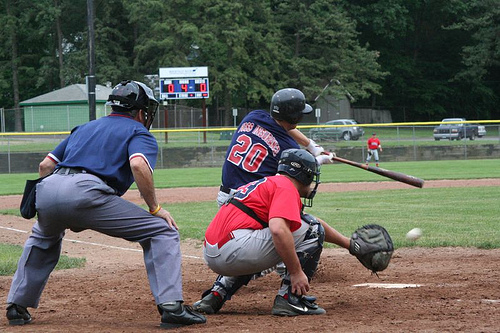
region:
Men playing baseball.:
[0, 7, 496, 327]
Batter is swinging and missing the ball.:
[218, 87, 421, 274]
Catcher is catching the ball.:
[182, 146, 423, 322]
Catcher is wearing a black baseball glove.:
[347, 222, 392, 272]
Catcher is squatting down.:
[185, 147, 391, 317]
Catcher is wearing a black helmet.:
[275, 146, 317, 184]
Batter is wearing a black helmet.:
[268, 85, 313, 121]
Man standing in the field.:
[361, 127, 383, 167]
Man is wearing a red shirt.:
[365, 135, 381, 148]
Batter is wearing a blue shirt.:
[217, 113, 299, 188]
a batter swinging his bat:
[207, 80, 430, 243]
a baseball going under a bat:
[351, 155, 441, 252]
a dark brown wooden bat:
[323, 148, 434, 196]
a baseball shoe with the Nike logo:
[268, 288, 327, 318]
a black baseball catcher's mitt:
[347, 218, 400, 275]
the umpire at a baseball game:
[8, 70, 209, 327]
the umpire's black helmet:
[105, 78, 161, 135]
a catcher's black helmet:
[273, 142, 328, 209]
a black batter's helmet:
[264, 84, 311, 135]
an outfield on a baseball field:
[363, 130, 385, 174]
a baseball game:
[6, 2, 496, 330]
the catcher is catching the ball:
[204, 157, 419, 328]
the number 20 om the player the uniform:
[227, 133, 265, 170]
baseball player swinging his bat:
[247, 95, 429, 188]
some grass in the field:
[428, 199, 497, 240]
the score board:
[160, 69, 212, 104]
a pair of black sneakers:
[3, 298, 203, 331]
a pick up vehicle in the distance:
[436, 118, 478, 144]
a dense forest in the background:
[4, 11, 495, 65]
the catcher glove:
[353, 227, 396, 274]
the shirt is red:
[204, 161, 320, 266]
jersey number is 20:
[207, 90, 288, 201]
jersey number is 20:
[225, 115, 283, 182]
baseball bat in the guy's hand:
[324, 145, 433, 190]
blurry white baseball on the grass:
[400, 223, 430, 248]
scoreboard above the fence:
[161, 76, 208, 96]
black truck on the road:
[433, 114, 485, 139]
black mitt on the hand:
[347, 211, 401, 277]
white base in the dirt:
[355, 271, 440, 301]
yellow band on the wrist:
[146, 205, 163, 217]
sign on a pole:
[312, 106, 319, 121]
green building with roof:
[21, 81, 100, 121]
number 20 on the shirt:
[226, 127, 266, 174]